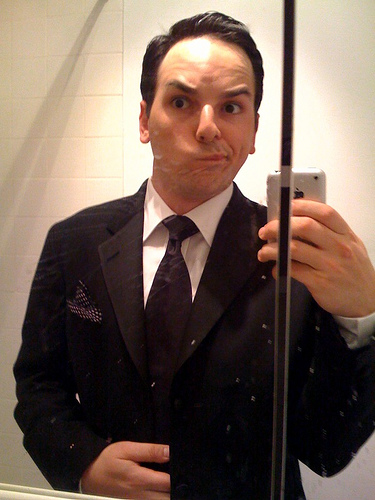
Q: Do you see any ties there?
A: Yes, there is a tie.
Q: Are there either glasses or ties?
A: Yes, there is a tie.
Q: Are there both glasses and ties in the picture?
A: No, there is a tie but no glasses.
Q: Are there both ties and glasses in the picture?
A: No, there is a tie but no glasses.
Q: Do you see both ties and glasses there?
A: No, there is a tie but no glasses.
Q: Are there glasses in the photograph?
A: No, there are no glasses.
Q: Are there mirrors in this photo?
A: Yes, there is a mirror.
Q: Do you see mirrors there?
A: Yes, there is a mirror.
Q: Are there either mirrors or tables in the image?
A: Yes, there is a mirror.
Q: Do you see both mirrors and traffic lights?
A: No, there is a mirror but no traffic lights.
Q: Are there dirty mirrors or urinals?
A: Yes, there is a dirty mirror.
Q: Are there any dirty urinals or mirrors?
A: Yes, there is a dirty mirror.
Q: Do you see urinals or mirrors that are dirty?
A: Yes, the mirror is dirty.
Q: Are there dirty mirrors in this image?
A: Yes, there is a dirty mirror.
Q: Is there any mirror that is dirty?
A: Yes, there is a mirror that is dirty.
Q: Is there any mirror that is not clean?
A: Yes, there is a dirty mirror.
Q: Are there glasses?
A: No, there are no glasses.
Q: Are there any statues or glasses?
A: No, there are no glasses or statues.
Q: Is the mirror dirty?
A: Yes, the mirror is dirty.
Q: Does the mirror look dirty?
A: Yes, the mirror is dirty.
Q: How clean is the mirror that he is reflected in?
A: The mirror is dirty.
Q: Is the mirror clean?
A: No, the mirror is dirty.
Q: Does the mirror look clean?
A: No, the mirror is dirty.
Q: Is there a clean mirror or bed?
A: No, there is a mirror but it is dirty.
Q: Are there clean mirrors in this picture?
A: No, there is a mirror but it is dirty.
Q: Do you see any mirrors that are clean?
A: No, there is a mirror but it is dirty.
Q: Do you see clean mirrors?
A: No, there is a mirror but it is dirty.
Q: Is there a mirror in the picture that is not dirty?
A: No, there is a mirror but it is dirty.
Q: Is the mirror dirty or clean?
A: The mirror is dirty.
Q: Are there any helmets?
A: No, there are no helmets.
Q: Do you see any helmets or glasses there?
A: No, there are no helmets or glasses.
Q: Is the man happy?
A: Yes, the man is happy.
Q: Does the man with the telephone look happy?
A: Yes, the man is happy.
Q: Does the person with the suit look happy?
A: Yes, the man is happy.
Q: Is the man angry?
A: No, the man is happy.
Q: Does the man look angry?
A: No, the man is happy.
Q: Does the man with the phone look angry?
A: No, the man is happy.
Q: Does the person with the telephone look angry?
A: No, the man is happy.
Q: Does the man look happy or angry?
A: The man is happy.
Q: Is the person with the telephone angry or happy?
A: The man is happy.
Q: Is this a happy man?
A: Yes, this is a happy man.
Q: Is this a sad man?
A: No, this is a happy man.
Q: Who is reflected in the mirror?
A: The man is reflected in the mirror.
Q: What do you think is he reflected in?
A: The man is reflected in the mirror.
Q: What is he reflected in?
A: The man is reflected in the mirror.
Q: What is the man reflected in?
A: The man is reflected in the mirror.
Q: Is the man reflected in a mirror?
A: Yes, the man is reflected in a mirror.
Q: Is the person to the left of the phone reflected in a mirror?
A: Yes, the man is reflected in a mirror.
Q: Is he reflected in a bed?
A: No, the man is reflected in a mirror.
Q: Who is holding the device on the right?
A: The man is holding the telephone.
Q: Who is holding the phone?
A: The man is holding the telephone.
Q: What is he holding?
A: The man is holding the phone.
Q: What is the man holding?
A: The man is holding the phone.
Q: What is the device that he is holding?
A: The device is a phone.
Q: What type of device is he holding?
A: The man is holding the telephone.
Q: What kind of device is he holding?
A: The man is holding the telephone.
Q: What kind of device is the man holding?
A: The man is holding the telephone.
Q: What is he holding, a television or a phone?
A: The man is holding a phone.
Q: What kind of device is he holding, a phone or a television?
A: The man is holding a phone.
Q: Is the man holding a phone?
A: Yes, the man is holding a phone.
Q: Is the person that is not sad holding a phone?
A: Yes, the man is holding a phone.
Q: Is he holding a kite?
A: No, the man is holding a phone.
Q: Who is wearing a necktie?
A: The man is wearing a necktie.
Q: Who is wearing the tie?
A: The man is wearing a necktie.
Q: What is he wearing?
A: The man is wearing a necktie.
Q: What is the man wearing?
A: The man is wearing a necktie.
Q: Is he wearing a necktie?
A: Yes, the man is wearing a necktie.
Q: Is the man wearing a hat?
A: No, the man is wearing a necktie.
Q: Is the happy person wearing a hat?
A: No, the man is wearing a necktie.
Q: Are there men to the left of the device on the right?
A: Yes, there is a man to the left of the telephone.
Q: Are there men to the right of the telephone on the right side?
A: No, the man is to the left of the telephone.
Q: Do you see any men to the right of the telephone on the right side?
A: No, the man is to the left of the telephone.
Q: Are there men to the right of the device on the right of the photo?
A: No, the man is to the left of the telephone.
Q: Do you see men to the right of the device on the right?
A: No, the man is to the left of the telephone.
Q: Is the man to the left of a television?
A: No, the man is to the left of the phone.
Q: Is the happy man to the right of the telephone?
A: No, the man is to the left of the telephone.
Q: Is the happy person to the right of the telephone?
A: No, the man is to the left of the telephone.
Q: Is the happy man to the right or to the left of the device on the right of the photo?
A: The man is to the left of the telephone.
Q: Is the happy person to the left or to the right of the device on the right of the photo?
A: The man is to the left of the telephone.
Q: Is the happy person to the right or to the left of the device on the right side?
A: The man is to the left of the telephone.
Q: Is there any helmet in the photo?
A: No, there are no helmets.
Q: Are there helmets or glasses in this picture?
A: No, there are no helmets or glasses.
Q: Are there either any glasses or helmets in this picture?
A: No, there are no helmets or glasses.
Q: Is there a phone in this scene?
A: Yes, there is a phone.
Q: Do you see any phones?
A: Yes, there is a phone.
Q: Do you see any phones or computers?
A: Yes, there is a phone.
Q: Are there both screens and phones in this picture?
A: No, there is a phone but no screens.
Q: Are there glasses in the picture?
A: No, there are no glasses.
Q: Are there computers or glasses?
A: No, there are no glasses or computers.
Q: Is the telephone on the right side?
A: Yes, the telephone is on the right of the image.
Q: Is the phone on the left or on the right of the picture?
A: The phone is on the right of the image.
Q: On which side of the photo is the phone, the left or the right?
A: The phone is on the right of the image.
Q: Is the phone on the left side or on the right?
A: The phone is on the right of the image.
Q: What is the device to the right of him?
A: The device is a phone.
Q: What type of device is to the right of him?
A: The device is a phone.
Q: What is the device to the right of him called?
A: The device is a phone.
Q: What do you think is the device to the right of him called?
A: The device is a phone.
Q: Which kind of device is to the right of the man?
A: The device is a phone.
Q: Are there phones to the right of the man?
A: Yes, there is a phone to the right of the man.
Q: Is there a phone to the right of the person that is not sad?
A: Yes, there is a phone to the right of the man.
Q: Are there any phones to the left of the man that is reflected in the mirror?
A: No, the phone is to the right of the man.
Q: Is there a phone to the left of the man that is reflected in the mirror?
A: No, the phone is to the right of the man.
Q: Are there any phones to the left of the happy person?
A: No, the phone is to the right of the man.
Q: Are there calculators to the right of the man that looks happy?
A: No, there is a phone to the right of the man.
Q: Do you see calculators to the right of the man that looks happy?
A: No, there is a phone to the right of the man.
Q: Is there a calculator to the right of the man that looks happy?
A: No, there is a phone to the right of the man.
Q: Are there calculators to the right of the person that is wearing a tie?
A: No, there is a phone to the right of the man.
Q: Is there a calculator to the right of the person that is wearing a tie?
A: No, there is a phone to the right of the man.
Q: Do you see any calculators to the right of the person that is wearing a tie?
A: No, there is a phone to the right of the man.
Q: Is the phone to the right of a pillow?
A: No, the phone is to the right of a man.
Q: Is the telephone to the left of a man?
A: No, the telephone is to the right of a man.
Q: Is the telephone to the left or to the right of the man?
A: The telephone is to the right of the man.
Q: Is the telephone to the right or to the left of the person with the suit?
A: The telephone is to the right of the man.